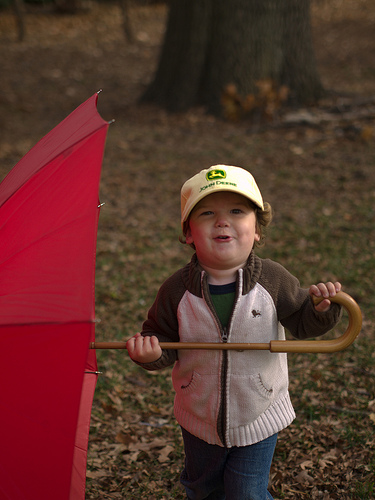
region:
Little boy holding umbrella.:
[121, 159, 344, 498]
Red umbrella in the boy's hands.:
[1, 83, 364, 497]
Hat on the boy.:
[167, 159, 269, 267]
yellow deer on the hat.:
[204, 166, 226, 180]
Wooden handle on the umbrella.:
[95, 286, 368, 362]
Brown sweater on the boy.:
[124, 162, 345, 453]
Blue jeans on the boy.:
[126, 163, 340, 496]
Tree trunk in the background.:
[130, 3, 336, 131]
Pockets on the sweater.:
[174, 368, 276, 438]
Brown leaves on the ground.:
[0, 0, 374, 497]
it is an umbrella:
[3, 101, 361, 498]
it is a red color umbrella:
[1, 89, 103, 498]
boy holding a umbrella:
[3, 102, 357, 495]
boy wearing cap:
[174, 161, 269, 226]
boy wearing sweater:
[130, 251, 340, 437]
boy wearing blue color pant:
[176, 428, 281, 494]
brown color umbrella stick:
[90, 288, 364, 363]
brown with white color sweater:
[137, 264, 327, 444]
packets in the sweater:
[178, 371, 278, 428]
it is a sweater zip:
[217, 324, 232, 344]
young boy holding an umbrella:
[0, 87, 364, 497]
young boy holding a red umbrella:
[0, 83, 367, 498]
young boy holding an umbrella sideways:
[4, 87, 374, 499]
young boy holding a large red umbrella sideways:
[1, 85, 373, 499]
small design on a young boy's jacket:
[248, 308, 262, 320]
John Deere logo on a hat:
[204, 167, 229, 179]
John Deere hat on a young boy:
[178, 164, 266, 226]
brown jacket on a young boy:
[138, 250, 337, 449]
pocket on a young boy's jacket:
[228, 373, 275, 429]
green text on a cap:
[196, 178, 243, 194]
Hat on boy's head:
[169, 155, 275, 271]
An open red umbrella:
[0, 87, 367, 498]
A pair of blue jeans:
[177, 423, 278, 498]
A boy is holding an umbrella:
[1, 84, 364, 497]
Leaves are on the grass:
[2, 1, 370, 498]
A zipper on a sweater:
[214, 321, 232, 344]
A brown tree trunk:
[128, 2, 335, 130]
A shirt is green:
[204, 280, 243, 332]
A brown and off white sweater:
[131, 251, 344, 449]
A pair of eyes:
[196, 206, 246, 223]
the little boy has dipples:
[239, 226, 255, 243]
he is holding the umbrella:
[135, 298, 281, 363]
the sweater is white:
[234, 380, 258, 400]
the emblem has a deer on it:
[203, 165, 229, 182]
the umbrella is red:
[25, 374, 50, 405]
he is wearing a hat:
[177, 160, 262, 224]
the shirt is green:
[215, 300, 230, 311]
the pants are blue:
[236, 454, 259, 477]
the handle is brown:
[215, 337, 266, 354]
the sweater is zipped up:
[213, 322, 236, 364]